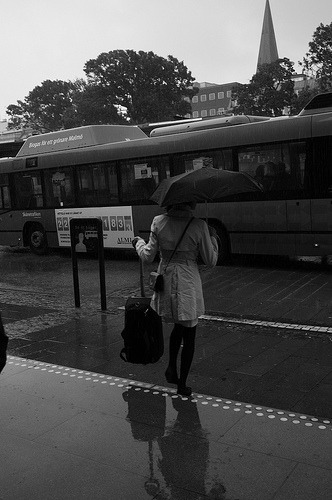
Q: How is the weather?
A: Raining.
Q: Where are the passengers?
A: On bus.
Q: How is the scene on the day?
A: Rainy.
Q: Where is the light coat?
A: On lady.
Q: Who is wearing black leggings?
A: A woman.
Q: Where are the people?
A: Inside bus.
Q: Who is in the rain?
A: A woman.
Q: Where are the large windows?
A: On bus.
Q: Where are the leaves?
A: On trees.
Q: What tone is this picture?
A: Black and white.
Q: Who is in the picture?
A: A woman.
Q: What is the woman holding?
A: An umbrella.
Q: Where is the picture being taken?
A: Bus station.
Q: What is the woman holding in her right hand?
A: Umbrella.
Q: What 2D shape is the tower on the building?
A: Triangle.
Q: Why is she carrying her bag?
A: Rain.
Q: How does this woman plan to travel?
A: By bus.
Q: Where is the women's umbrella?
A: Over her head.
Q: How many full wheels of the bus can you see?
A: 2.